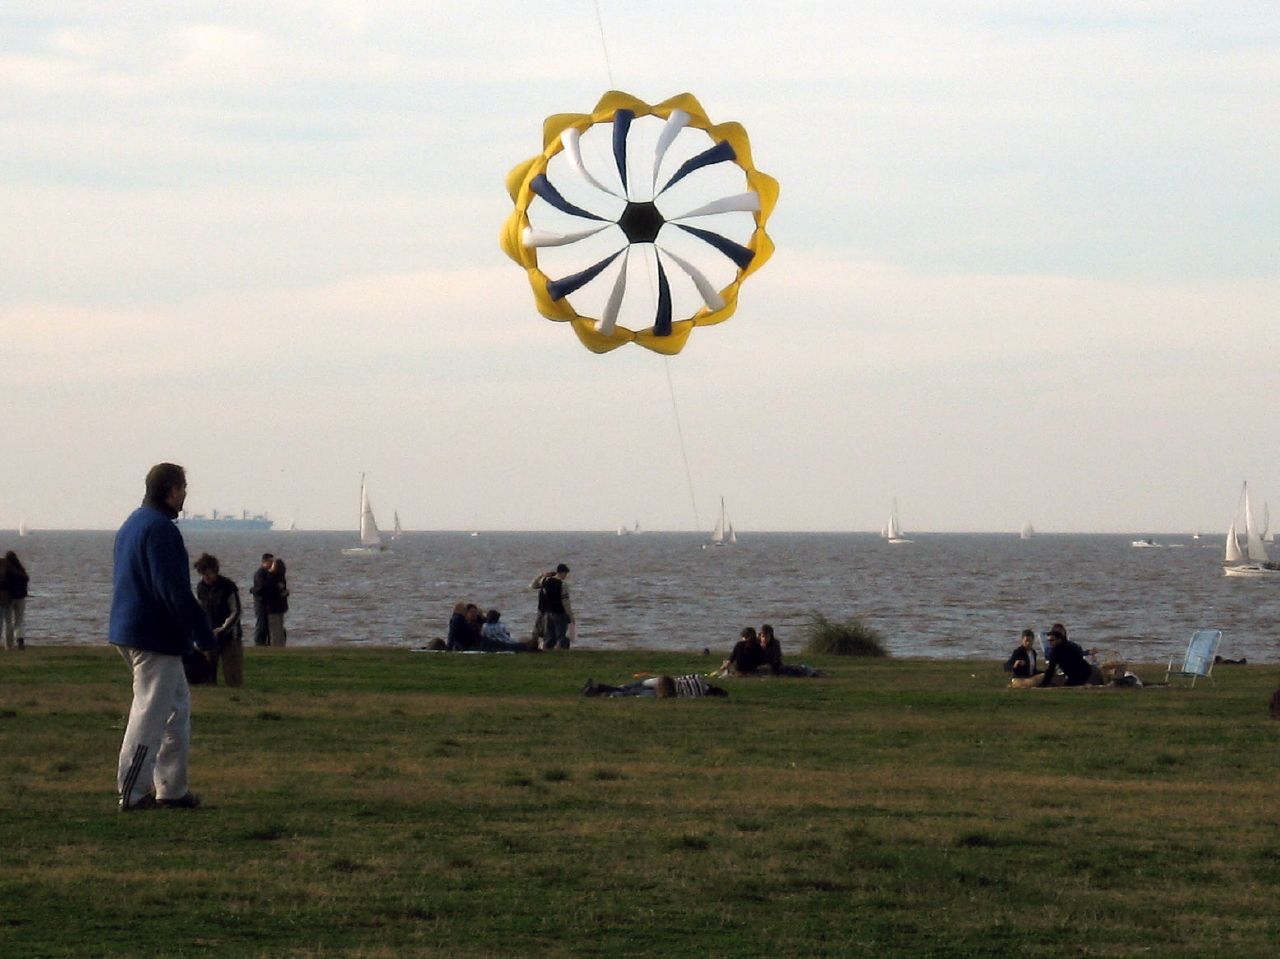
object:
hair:
[143, 461, 186, 499]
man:
[100, 462, 222, 811]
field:
[18, 623, 1237, 914]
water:
[305, 549, 1154, 643]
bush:
[810, 610, 882, 661]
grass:
[1159, 851, 1226, 904]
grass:
[18, 761, 65, 831]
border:
[494, 83, 795, 352]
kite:
[494, 89, 801, 358]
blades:
[601, 106, 642, 205]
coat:
[108, 505, 212, 660]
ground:
[589, 749, 1068, 936]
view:
[463, 732, 839, 942]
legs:
[111, 655, 171, 813]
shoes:
[105, 794, 176, 814]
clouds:
[868, 208, 1112, 401]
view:
[882, 91, 1083, 427]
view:
[416, 60, 1036, 531]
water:
[630, 558, 833, 680]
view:
[567, 527, 719, 617]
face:
[177, 470, 188, 509]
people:
[480, 608, 510, 652]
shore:
[37, 620, 1232, 745]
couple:
[248, 540, 295, 650]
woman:
[1046, 623, 1093, 675]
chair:
[1037, 630, 1099, 685]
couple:
[530, 562, 579, 653]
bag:
[172, 638, 216, 685]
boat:
[333, 471, 384, 574]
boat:
[1219, 481, 1280, 583]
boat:
[879, 496, 916, 546]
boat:
[695, 485, 736, 552]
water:
[8, 518, 1239, 657]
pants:
[113, 643, 191, 803]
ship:
[173, 505, 277, 534]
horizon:
[4, 516, 1280, 559]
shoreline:
[32, 640, 1230, 673]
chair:
[1164, 630, 1225, 691]